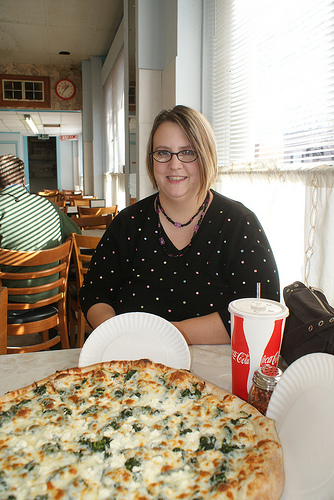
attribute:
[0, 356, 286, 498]
pizza — large, cheese, white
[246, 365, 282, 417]
jar — red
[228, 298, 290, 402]
cup — paper, red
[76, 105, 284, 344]
woman — sitting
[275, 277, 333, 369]
purse — black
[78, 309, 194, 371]
plate — paper, white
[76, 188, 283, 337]
shirt — black, polka dot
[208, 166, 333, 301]
curtain — white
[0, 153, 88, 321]
man — sitting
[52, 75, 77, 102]
clock — red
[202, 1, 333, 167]
blinds — white, closed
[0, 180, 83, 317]
t-shirt — green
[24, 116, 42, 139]
light — on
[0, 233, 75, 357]
chair — wooden